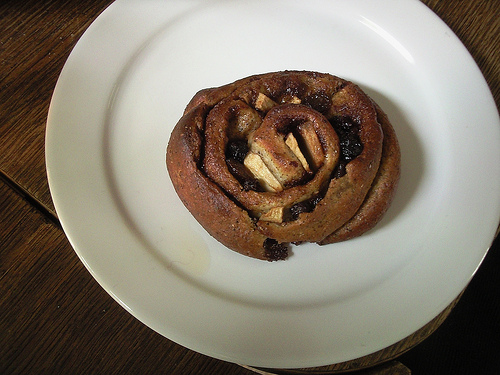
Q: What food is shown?
A: A fruit roll.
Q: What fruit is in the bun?
A: Raisins and apples.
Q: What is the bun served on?
A: A plate.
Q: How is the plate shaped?
A: Roundly.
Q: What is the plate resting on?
A: A table.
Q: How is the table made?
A: Of wood.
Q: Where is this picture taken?
A: A kitchen.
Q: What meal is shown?
A: Breakfast.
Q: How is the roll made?
A: Through twisting.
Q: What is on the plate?
A: Cinnamon bun.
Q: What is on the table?
A: Plate.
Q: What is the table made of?
A: Wood.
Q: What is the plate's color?
A: White.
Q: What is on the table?
A: Plate.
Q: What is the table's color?
A: Brown.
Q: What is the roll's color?
A: Brown.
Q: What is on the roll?
A: Raisin.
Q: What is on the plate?
A: Pastry.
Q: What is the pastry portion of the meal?
A: Dessert.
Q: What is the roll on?
A: A plate.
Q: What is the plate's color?
A: White.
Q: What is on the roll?
A: Raisins.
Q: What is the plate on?
A: Table.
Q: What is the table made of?
A: Wood.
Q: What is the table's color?
A: Brown.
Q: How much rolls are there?
A: 1.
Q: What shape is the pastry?
A: Round.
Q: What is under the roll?
A: A white plate.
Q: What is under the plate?
A: A wooden table.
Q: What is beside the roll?
A: The shadow of the roll.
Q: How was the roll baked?
A: Baked till it is brown.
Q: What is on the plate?
A: Pastry.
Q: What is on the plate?
A: Cinnamon roll.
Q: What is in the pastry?
A: Raisins.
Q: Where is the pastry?
A: On a plate.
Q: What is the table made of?
A: Wood.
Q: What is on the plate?
A: A danish.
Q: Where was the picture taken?
A: Inside.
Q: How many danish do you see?
A: 1.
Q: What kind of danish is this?
A: A raisin danish.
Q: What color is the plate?
A: The plate is white.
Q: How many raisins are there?
A: 9 raisins.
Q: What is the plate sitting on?
A: A wooden table.